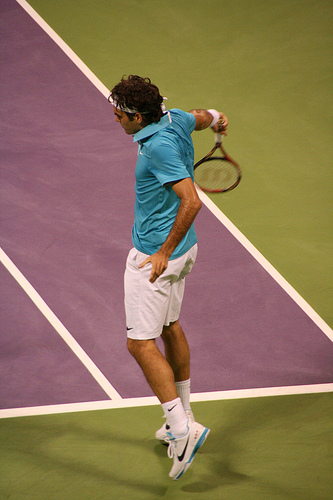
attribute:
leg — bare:
[161, 312, 194, 387]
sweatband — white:
[90, 103, 165, 113]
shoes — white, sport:
[156, 414, 218, 489]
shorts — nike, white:
[100, 235, 212, 342]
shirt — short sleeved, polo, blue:
[109, 127, 208, 263]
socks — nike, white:
[166, 393, 179, 445]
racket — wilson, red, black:
[186, 107, 237, 203]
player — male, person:
[59, 28, 254, 493]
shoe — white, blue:
[150, 404, 248, 474]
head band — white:
[105, 95, 165, 118]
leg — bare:
[141, 340, 172, 407]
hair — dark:
[111, 69, 170, 122]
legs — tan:
[89, 324, 214, 396]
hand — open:
[139, 246, 172, 284]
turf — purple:
[1, 38, 95, 250]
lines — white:
[41, 9, 87, 114]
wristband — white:
[207, 105, 221, 134]